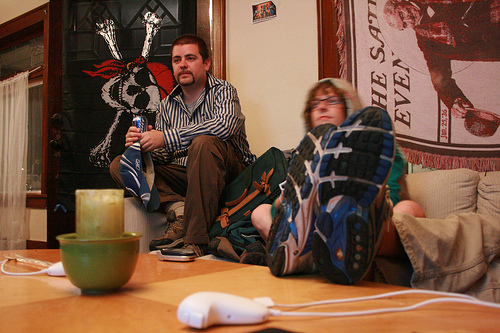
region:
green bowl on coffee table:
[54, 232, 143, 294]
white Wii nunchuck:
[174, 291, 272, 328]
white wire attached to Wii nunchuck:
[266, 295, 498, 317]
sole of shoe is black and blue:
[311, 104, 395, 284]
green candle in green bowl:
[75, 185, 127, 237]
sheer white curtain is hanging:
[2, 73, 28, 250]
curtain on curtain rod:
[0, 64, 45, 81]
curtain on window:
[1, 23, 43, 193]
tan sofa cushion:
[401, 169, 478, 216]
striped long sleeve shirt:
[152, 75, 248, 162]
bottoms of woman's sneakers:
[264, 101, 397, 286]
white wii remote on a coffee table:
[173, 285, 499, 330]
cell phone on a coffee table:
[153, 242, 199, 267]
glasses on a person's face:
[309, 95, 342, 110]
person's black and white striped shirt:
[148, 74, 253, 172]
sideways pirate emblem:
[87, 9, 171, 166]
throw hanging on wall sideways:
[333, 1, 499, 193]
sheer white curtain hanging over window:
[1, 71, 32, 258]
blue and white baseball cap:
[112, 139, 167, 212]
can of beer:
[129, 110, 148, 140]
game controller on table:
[166, 270, 498, 332]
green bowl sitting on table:
[55, 230, 143, 295]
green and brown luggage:
[204, 145, 292, 237]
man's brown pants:
[108, 134, 248, 244]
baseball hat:
[116, 139, 166, 214]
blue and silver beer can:
[131, 113, 148, 140]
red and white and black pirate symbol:
[86, 7, 178, 175]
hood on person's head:
[296, 70, 363, 130]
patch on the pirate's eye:
[133, 66, 155, 91]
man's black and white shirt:
[141, 70, 252, 163]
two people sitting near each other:
[110, 36, 414, 283]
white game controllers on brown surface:
[3, 243, 383, 330]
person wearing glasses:
[297, 85, 347, 112]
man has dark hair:
[155, 32, 220, 90]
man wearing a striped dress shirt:
[141, 38, 245, 158]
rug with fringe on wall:
[291, 1, 498, 177]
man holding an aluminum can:
[122, 41, 228, 148]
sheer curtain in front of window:
[0, 58, 40, 255]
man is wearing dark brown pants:
[103, 130, 251, 251]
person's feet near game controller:
[176, 105, 413, 331]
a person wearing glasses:
[285, 71, 442, 271]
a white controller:
[174, 269, 498, 325]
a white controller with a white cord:
[176, 260, 497, 325]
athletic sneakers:
[243, 102, 420, 311]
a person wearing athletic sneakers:
[264, 72, 428, 279]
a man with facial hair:
[150, 36, 277, 208]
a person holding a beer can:
[105, 20, 248, 180]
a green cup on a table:
[36, 192, 161, 302]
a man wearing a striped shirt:
[141, 40, 283, 198]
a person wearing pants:
[143, 46, 310, 258]